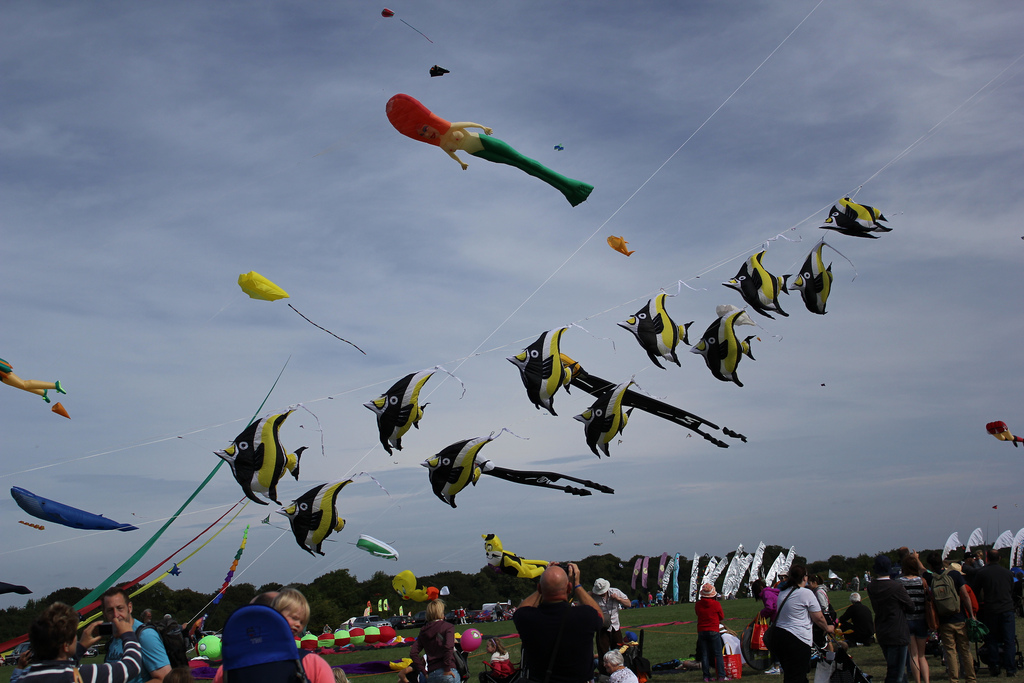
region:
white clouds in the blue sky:
[702, 94, 794, 148]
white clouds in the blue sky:
[66, 284, 136, 358]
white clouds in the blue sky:
[208, 122, 294, 190]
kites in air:
[145, 197, 886, 546]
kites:
[332, 77, 612, 226]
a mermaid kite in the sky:
[384, 93, 593, 210]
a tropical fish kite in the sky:
[218, 402, 305, 510]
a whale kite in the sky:
[9, 483, 137, 534]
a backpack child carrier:
[216, 603, 311, 679]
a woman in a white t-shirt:
[774, 567, 838, 679]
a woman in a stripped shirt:
[0, 608, 143, 679]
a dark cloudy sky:
[3, 4, 1021, 614]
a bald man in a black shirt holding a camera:
[514, 557, 609, 679]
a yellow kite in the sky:
[239, 271, 296, 307]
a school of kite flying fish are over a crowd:
[192, 205, 892, 550]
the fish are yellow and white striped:
[223, 367, 436, 554]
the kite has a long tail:
[512, 320, 754, 463]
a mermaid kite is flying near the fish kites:
[376, 82, 598, 222]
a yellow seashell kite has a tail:
[224, 259, 301, 314]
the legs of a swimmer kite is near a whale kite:
[0, 351, 83, 428]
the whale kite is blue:
[6, 473, 143, 549]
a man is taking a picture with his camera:
[503, 550, 620, 678]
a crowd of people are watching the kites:
[686, 552, 1020, 673]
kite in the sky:
[715, 246, 843, 316]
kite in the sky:
[699, 294, 766, 390]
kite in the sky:
[494, 328, 586, 417]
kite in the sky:
[335, 369, 434, 450]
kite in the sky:
[207, 399, 309, 492]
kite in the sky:
[231, 240, 364, 354]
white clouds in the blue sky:
[822, 367, 883, 443]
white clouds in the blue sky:
[778, 69, 848, 115]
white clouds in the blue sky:
[658, 69, 751, 145]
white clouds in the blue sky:
[131, 177, 224, 232]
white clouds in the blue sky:
[222, 133, 300, 188]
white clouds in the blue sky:
[2, 165, 124, 238]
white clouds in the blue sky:
[70, 69, 131, 153]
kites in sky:
[122, 57, 920, 554]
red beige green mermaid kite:
[381, 89, 596, 210]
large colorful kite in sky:
[368, 86, 596, 232]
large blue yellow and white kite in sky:
[819, 195, 906, 241]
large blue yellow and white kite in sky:
[181, 391, 330, 522]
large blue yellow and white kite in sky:
[272, 487, 356, 554]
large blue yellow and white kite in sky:
[348, 361, 435, 451]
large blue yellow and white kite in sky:
[418, 426, 552, 519]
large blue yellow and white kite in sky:
[491, 329, 610, 425]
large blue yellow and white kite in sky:
[570, 379, 654, 457]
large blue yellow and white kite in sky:
[611, 288, 684, 375]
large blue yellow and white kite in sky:
[684, 282, 757, 378]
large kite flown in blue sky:
[209, 247, 290, 320]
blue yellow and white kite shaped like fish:
[207, 405, 309, 498]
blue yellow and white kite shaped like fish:
[260, 478, 338, 545]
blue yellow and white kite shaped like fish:
[355, 358, 420, 451]